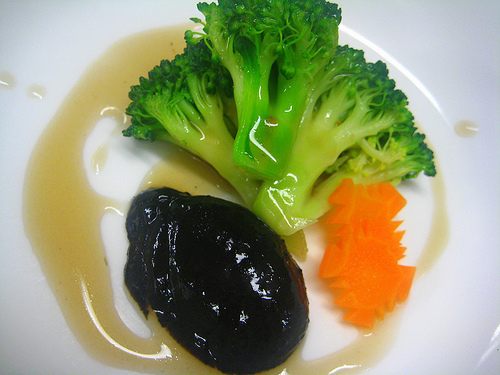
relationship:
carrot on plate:
[320, 178, 416, 332] [36, 73, 495, 375]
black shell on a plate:
[127, 185, 307, 373] [0, 0, 495, 374]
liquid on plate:
[26, 37, 447, 371] [0, 0, 495, 374]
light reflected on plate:
[339, 21, 447, 120] [0, 0, 495, 374]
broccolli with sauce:
[120, 0, 435, 237] [193, 79, 387, 233]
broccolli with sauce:
[120, 0, 435, 237] [192, 83, 379, 226]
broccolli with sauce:
[253, 45, 435, 237] [284, 108, 369, 224]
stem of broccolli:
[233, 81, 308, 178] [120, 0, 435, 237]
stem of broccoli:
[301, 132, 320, 199] [241, 52, 431, 242]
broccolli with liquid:
[120, 0, 435, 237] [21, 21, 453, 375]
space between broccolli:
[263, 59, 285, 106] [120, 0, 435, 237]